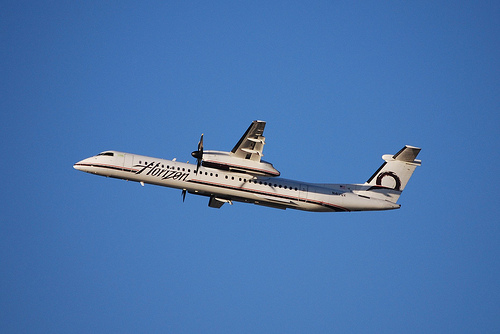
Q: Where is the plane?
A: In sky.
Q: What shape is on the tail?
A: Circle.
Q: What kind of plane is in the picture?
A: A passenger plane.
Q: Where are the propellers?
A: On wings.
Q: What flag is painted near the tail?
A: American Flag.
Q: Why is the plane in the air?
A: For transportation.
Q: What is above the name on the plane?
A: Windows.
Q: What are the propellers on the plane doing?
A: Spinning.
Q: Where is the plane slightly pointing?
A: Up.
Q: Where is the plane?
A: In the sky.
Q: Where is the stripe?
A: On the down side.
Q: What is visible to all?
A: The sky.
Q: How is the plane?
A: Visible.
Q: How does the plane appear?
A: Visible.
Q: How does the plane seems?
A: Visible to all.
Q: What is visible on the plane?
A: The windows.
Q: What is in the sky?
A: Plane.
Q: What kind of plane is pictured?
A: Passenger.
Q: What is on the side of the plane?
A: Writing.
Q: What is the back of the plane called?
A: Tail.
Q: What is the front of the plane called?
A: Cockpit.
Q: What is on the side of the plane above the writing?
A: Windows.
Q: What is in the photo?
A: Airplane.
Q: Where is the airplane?
A: In the sky.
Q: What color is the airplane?
A: White.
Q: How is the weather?
A: Sunny.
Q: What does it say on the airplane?
A: Horizon.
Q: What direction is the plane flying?
A: Right to left.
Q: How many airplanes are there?
A: One.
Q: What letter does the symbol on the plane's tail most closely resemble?
A: O.